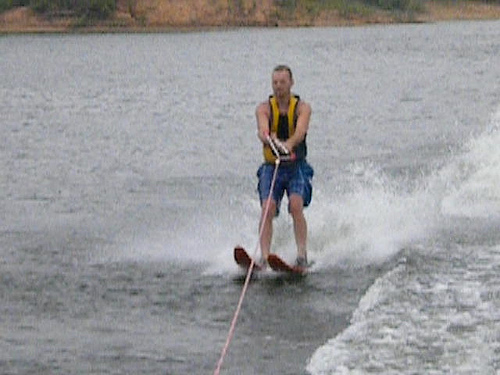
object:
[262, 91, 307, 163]
life vest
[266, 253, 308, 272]
ski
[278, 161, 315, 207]
shorts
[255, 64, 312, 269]
man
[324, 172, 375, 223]
ground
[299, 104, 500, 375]
wake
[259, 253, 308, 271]
feet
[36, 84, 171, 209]
water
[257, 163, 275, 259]
leg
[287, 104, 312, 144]
arm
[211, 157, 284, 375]
rope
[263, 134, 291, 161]
object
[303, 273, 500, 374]
bubbles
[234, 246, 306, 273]
water skis